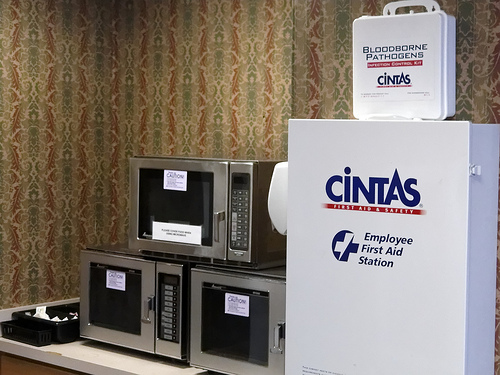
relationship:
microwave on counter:
[71, 142, 286, 312] [35, 298, 129, 373]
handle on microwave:
[199, 202, 235, 248] [71, 142, 286, 312]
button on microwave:
[233, 182, 263, 226] [71, 142, 286, 312]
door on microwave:
[157, 185, 213, 235] [71, 142, 286, 312]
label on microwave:
[154, 166, 197, 192] [71, 142, 286, 312]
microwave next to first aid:
[71, 142, 286, 312] [284, 120, 440, 295]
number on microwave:
[226, 197, 243, 231] [71, 142, 286, 312]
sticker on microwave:
[135, 214, 204, 266] [71, 142, 286, 312]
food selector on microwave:
[152, 263, 188, 309] [71, 142, 286, 312]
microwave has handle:
[71, 142, 286, 312] [199, 202, 235, 248]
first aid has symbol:
[349, 25, 458, 123] [336, 223, 361, 260]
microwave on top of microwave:
[126, 152, 287, 270] [71, 241, 189, 365]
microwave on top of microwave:
[126, 152, 287, 270] [76, 245, 187, 360]